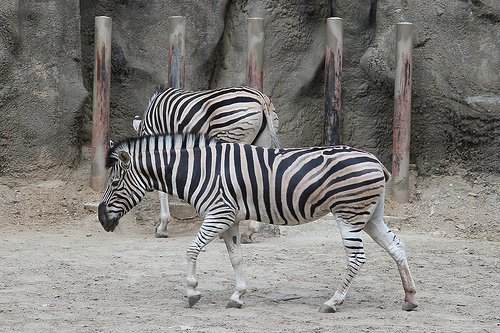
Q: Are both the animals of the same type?
A: Yes, all the animals are zebras.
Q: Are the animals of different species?
A: No, all the animals are zebras.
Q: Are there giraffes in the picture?
A: No, there are no giraffes.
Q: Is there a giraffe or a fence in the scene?
A: No, there are no giraffes or fences.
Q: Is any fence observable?
A: No, there are no fences.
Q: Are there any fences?
A: No, there are no fences.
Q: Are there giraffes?
A: No, there are no giraffes.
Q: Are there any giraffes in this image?
A: No, there are no giraffes.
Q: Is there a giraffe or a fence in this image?
A: No, there are no giraffes or fences.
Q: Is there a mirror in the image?
A: No, there are no mirrors.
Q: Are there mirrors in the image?
A: No, there are no mirrors.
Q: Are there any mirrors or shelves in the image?
A: No, there are no mirrors or shelves.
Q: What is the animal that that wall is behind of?
A: The animal is a zebra.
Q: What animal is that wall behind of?
A: The wall is behind the zebra.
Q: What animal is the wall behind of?
A: The wall is behind the zebra.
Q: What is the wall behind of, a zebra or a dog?
A: The wall is behind a zebra.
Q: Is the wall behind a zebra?
A: Yes, the wall is behind a zebra.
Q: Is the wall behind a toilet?
A: No, the wall is behind a zebra.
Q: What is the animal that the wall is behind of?
A: The animal is a zebra.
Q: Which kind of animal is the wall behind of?
A: The wall is behind the zebra.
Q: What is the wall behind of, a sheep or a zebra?
A: The wall is behind a zebra.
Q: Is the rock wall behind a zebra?
A: Yes, the wall is behind a zebra.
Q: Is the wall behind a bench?
A: No, the wall is behind a zebra.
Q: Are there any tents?
A: No, there are no tents.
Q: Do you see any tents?
A: No, there are no tents.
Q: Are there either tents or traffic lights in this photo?
A: No, there are no tents or traffic lights.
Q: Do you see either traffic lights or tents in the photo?
A: No, there are no tents or traffic lights.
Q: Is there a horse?
A: No, there are no horses.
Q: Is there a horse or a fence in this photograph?
A: No, there are no horses or fences.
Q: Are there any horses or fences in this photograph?
A: No, there are no horses or fences.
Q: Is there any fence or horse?
A: No, there are no horses or fences.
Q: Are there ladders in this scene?
A: No, there are no ladders.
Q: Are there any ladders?
A: No, there are no ladders.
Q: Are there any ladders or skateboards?
A: No, there are no ladders or skateboards.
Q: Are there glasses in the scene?
A: No, there are no glasses.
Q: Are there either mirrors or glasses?
A: No, there are no glasses or mirrors.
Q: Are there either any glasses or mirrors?
A: No, there are no glasses or mirrors.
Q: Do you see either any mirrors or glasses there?
A: No, there are no glasses or mirrors.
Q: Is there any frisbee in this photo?
A: No, there are no frisbees.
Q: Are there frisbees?
A: No, there are no frisbees.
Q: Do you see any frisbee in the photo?
A: No, there are no frisbees.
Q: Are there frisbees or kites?
A: No, there are no frisbees or kites.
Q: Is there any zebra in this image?
A: Yes, there is a zebra.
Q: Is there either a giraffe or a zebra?
A: Yes, there is a zebra.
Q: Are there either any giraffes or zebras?
A: Yes, there is a zebra.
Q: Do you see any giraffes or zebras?
A: Yes, there is a zebra.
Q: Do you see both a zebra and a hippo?
A: No, there is a zebra but no hippoes.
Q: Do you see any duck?
A: No, there are no ducks.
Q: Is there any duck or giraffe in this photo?
A: No, there are no ducks or giraffes.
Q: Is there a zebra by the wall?
A: Yes, there is a zebra by the wall.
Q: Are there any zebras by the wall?
A: Yes, there is a zebra by the wall.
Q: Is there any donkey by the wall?
A: No, there is a zebra by the wall.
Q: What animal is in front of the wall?
A: The zebra is in front of the wall.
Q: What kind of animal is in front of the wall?
A: The animal is a zebra.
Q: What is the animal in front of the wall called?
A: The animal is a zebra.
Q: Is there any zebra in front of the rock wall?
A: Yes, there is a zebra in front of the wall.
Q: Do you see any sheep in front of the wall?
A: No, there is a zebra in front of the wall.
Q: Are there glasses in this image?
A: No, there are no glasses.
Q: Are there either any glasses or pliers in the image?
A: No, there are no glasses or pliers.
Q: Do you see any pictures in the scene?
A: No, there are no pictures.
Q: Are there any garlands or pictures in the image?
A: No, there are no pictures or garlands.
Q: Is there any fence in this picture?
A: No, there are no fences.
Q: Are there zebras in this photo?
A: Yes, there is a zebra.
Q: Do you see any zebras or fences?
A: Yes, there is a zebra.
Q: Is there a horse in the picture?
A: No, there are no horses.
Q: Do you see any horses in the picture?
A: No, there are no horses.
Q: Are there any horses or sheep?
A: No, there are no horses or sheep.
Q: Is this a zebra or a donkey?
A: This is a zebra.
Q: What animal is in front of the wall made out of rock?
A: The zebra is in front of the wall.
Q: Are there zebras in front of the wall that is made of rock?
A: Yes, there is a zebra in front of the wall.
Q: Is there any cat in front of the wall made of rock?
A: No, there is a zebra in front of the wall.